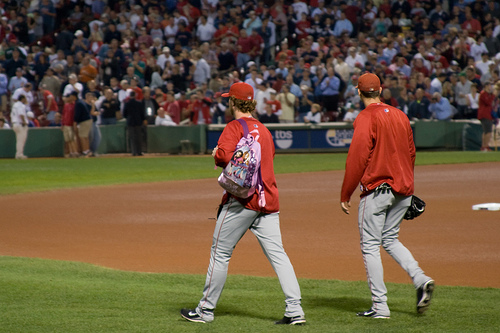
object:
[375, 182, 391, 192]
glove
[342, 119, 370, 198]
arm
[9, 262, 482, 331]
grass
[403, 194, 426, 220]
glove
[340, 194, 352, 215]
hand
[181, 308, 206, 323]
shoe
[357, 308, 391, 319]
shoe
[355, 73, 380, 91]
baseball cap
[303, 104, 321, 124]
boy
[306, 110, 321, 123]
shirt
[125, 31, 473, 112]
fans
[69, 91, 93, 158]
man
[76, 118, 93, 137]
shorts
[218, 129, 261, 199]
backpack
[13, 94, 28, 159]
man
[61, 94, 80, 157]
man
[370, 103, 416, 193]
back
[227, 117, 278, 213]
back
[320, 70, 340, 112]
man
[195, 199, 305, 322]
pants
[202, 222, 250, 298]
leg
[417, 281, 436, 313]
cleats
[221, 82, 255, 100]
cap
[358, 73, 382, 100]
head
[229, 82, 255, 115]
head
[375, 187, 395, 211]
back pocket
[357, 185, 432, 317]
pants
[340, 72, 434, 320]
baseball player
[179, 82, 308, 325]
baseball player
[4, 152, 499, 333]
field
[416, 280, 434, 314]
feet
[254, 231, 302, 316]
leg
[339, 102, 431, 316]
uniform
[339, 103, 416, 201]
jacket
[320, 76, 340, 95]
shirt